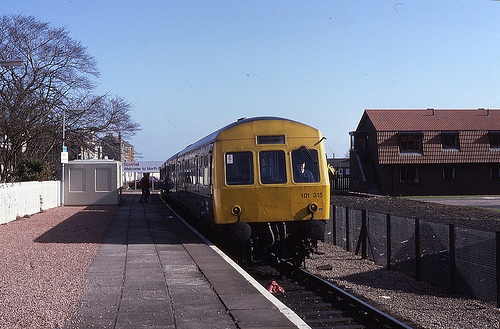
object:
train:
[158, 116, 330, 272]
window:
[225, 153, 255, 187]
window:
[259, 151, 286, 186]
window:
[292, 149, 320, 183]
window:
[257, 135, 286, 145]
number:
[299, 191, 324, 200]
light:
[233, 205, 241, 214]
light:
[309, 204, 317, 213]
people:
[140, 170, 153, 202]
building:
[62, 159, 123, 207]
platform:
[0, 192, 313, 329]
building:
[348, 109, 499, 197]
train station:
[1, 158, 500, 329]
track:
[273, 256, 425, 329]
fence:
[324, 202, 500, 306]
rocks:
[1, 205, 112, 328]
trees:
[0, 15, 101, 180]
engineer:
[296, 160, 317, 182]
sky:
[0, 1, 499, 161]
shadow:
[33, 179, 215, 245]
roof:
[367, 108, 500, 130]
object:
[267, 279, 284, 296]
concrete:
[398, 194, 500, 208]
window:
[399, 167, 419, 181]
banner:
[121, 164, 162, 173]